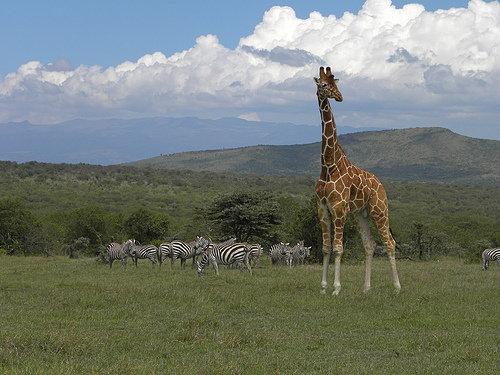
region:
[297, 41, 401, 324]
a very tall giraffe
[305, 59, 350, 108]
a giraffe with two horns on its head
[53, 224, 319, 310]
several zebra's in a field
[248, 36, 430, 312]
a giraffe standing in a field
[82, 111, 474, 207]
a hillside covered with grass and trees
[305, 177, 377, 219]
pattern of spots on giraffe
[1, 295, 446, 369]
a grassy field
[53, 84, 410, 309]
zebra's and giraffe standing in a field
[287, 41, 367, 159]
a giraffe with its head turned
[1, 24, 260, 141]
white clouds in a blue sky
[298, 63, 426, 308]
giraffe standing on the grass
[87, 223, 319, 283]
a herd of zebras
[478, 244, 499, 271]
black and white zebra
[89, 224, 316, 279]
zebras standing on the grass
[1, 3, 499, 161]
blue sky with big puffy clouds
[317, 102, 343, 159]
brown spots along the neck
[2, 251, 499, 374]
green grass on the ground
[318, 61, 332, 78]
two tiny horns on the head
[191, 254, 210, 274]
head bent down towards the ground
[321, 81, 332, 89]
small black eye on the side of the head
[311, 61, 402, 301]
a giraffe standing in a field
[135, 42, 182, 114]
the clouds in the sky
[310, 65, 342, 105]
a head of a giraffe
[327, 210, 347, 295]
the front leg of a giraffe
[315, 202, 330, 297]
the front leg of a giraffe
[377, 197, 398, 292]
the hind leg of a giraffe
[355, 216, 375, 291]
the hind leg of a giraffe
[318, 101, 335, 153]
the neck of a giraffe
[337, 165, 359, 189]
the spots of a giraffe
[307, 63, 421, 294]
A very tall giraffe in the field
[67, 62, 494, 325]
Multiple species of animals in an open field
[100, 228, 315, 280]
A group of zebras behind the giraffe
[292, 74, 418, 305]
The giraffe is yellow and black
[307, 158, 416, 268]
Brown spots on the giraffe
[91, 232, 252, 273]
The zebras have stripes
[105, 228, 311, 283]
The zebras are black and white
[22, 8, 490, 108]
Thick white clouds in the sky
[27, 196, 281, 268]
Trees growing in the distance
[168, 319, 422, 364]
Grass growing on the ground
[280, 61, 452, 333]
giraffe is on grass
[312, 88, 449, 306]
brown and white spots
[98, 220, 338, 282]
zebras are behind giraffe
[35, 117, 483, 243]
tall brown and green mountain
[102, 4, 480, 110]
puffy white and grey clouds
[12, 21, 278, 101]
sky is white and blue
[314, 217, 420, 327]
giraffe has white legs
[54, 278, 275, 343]
grass is short and green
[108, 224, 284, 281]
black and white stripes on zebras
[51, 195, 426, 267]
green trees behind zebras